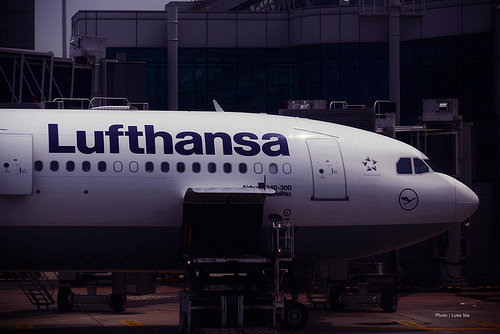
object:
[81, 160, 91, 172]
window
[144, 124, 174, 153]
letter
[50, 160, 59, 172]
window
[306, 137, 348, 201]
door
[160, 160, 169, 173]
window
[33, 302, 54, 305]
stairs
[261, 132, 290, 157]
letter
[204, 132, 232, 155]
letter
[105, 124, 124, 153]
blue letter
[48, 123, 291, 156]
lufthansa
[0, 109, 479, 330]
plane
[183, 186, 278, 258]
compartment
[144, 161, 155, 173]
window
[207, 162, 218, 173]
window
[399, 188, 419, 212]
logo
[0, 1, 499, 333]
hangar